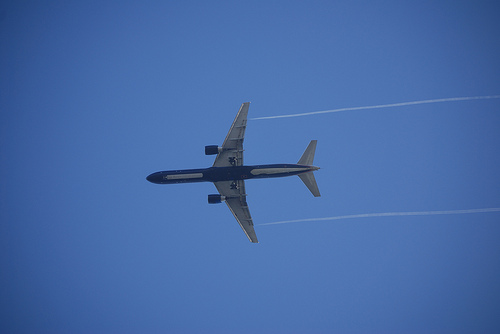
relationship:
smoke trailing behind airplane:
[243, 90, 498, 121] [144, 102, 321, 243]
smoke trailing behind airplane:
[254, 205, 498, 227] [144, 102, 321, 243]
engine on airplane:
[203, 143, 233, 155] [144, 102, 321, 243]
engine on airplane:
[206, 188, 231, 205] [144, 102, 321, 243]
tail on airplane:
[289, 139, 333, 202] [144, 102, 321, 243]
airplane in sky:
[144, 102, 321, 243] [17, 7, 489, 319]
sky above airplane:
[0, 0, 500, 332] [145, 102, 323, 244]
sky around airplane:
[17, 7, 489, 319] [144, 102, 321, 243]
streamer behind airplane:
[242, 90, 497, 125] [145, 102, 323, 244]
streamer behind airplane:
[250, 203, 499, 235] [145, 102, 323, 244]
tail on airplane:
[289, 139, 339, 207] [145, 102, 323, 244]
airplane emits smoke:
[145, 102, 323, 244] [235, 95, 474, 122]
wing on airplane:
[208, 100, 258, 167] [144, 102, 321, 243]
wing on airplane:
[213, 180, 262, 241] [144, 102, 321, 243]